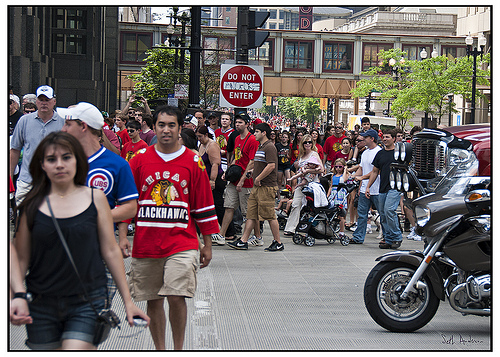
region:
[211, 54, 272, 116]
an interdiction sign on a pole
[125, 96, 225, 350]
man wears red top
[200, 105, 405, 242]
a crowd on the street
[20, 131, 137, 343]
woman wears a black top tank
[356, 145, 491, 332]
a motorcycle color black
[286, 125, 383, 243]
man pulling a stroller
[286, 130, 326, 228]
woman holding a baby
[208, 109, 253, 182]
two people wearing red tops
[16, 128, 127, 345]
woman has black hair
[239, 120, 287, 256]
man wears brown cloths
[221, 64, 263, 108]
sign says Do Not Enter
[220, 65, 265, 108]
sign is red and white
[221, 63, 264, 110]
letters on sign are white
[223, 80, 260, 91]
graffiti sprayed on sign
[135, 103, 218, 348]
man crossing busy street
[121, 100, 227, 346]
man has black hair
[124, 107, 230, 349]
man wearing Blackhawks jersey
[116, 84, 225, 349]
man wearing tan shorts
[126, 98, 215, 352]
man wearing red jersey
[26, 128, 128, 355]
woman carrying black purse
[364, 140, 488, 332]
a parked black motorcycle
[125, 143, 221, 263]
a red Chicago Blackhawks jersey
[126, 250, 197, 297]
a brown pair of shorts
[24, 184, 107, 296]
a woman's black tank top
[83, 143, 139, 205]
a blue Cubs jersey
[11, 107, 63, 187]
a man's blue short sleeve shirt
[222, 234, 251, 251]
a pair of black and white shoes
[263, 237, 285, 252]
a pair of black and white shoes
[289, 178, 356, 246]
a black baby stroller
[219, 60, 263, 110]
a red and white do not enter sign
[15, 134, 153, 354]
woman in black top with handheld device walking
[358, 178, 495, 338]
part of a motorcycle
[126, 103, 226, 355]
man in blackhawks jersey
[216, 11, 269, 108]
street sign on a pole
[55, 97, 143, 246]
man in hat and cubs jersey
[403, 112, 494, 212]
front end of a truck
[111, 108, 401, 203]
large crowd with many people wearing blackhawk jerseys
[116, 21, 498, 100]
skyway over the street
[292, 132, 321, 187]
woman in sunglasses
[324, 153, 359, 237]
little girl in pink framed sunglasses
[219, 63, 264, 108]
A red and white street sign.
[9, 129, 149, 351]
A yound brunette woman.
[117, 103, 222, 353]
A man in a red tshirt.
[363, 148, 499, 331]
A motorcycle parked on pavement.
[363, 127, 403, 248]
A young man walking.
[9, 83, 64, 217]
A man with a blue and white hat.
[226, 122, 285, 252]
A young man wearing brown.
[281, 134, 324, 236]
A woman carrying a child.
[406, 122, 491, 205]
The front end of a truck.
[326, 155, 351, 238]
A little girl wearing sunglasses.